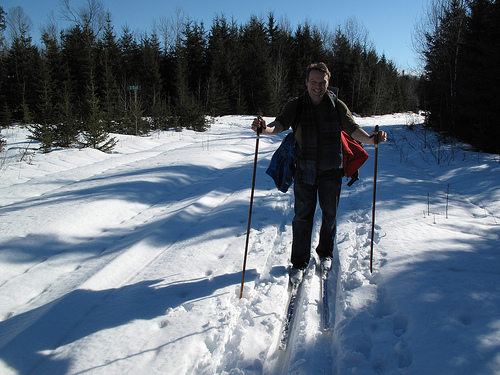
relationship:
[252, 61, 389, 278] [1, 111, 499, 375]
man standing in snow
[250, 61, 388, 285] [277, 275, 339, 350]
man wearing skis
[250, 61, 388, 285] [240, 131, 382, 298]
man holding on to poles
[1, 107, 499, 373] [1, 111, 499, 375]
ground covered by snow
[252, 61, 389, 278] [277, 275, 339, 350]
man wearing skis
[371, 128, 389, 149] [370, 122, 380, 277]
hand holding pole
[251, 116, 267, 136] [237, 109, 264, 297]
hand holding pole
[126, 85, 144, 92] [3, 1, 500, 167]
sign in background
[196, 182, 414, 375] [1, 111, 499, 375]
tracks are visible in snow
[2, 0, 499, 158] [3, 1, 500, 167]
trees are in background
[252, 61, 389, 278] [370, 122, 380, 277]
man holding pole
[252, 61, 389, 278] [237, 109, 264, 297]
man holding pole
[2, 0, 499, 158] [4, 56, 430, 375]
trees are standing beside road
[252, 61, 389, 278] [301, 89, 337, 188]
man wearing a scarf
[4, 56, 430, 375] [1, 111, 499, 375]
road covered with snow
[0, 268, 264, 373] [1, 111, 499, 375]
shadow appears on snow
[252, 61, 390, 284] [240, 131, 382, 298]
skier holding poles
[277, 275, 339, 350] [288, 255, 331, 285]
skis are attached to feet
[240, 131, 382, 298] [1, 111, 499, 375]
poles have left marks in snow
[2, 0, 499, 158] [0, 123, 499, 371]
trees have thrown shadows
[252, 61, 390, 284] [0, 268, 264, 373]
skier has a shadow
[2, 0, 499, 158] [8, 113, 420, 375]
trees are behind trail